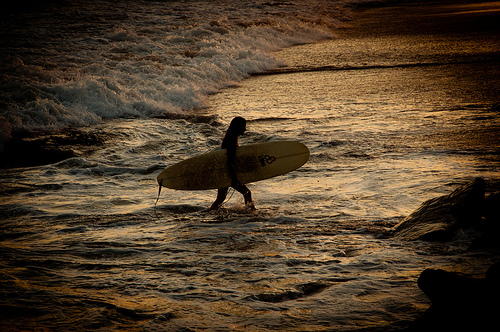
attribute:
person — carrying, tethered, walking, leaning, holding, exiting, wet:
[213, 113, 256, 212]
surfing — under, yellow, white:
[157, 137, 308, 190]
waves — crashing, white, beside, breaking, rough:
[24, 74, 214, 122]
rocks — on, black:
[417, 261, 499, 330]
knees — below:
[208, 187, 256, 207]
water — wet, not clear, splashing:
[177, 208, 286, 250]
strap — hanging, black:
[153, 179, 237, 207]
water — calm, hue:
[267, 67, 499, 138]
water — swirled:
[4, 139, 156, 200]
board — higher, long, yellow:
[248, 138, 311, 174]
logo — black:
[256, 152, 277, 164]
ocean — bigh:
[3, 1, 325, 328]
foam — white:
[124, 61, 204, 111]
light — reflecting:
[271, 73, 446, 123]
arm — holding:
[221, 136, 245, 191]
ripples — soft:
[277, 225, 401, 308]